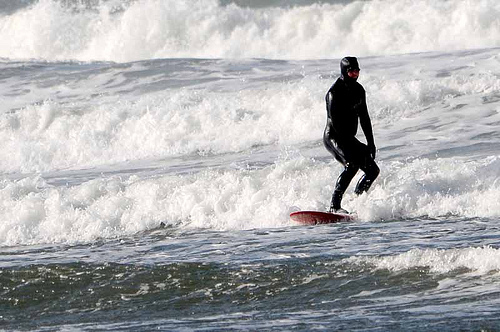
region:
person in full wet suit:
[313, 50, 410, 210]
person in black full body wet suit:
[323, 49, 395, 206]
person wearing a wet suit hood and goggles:
[338, 49, 368, 88]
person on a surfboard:
[282, 44, 403, 232]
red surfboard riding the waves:
[289, 206, 381, 238]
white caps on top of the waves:
[38, 175, 231, 238]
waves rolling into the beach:
[31, 26, 228, 254]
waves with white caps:
[41, 76, 223, 293]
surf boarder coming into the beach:
[274, 41, 406, 246]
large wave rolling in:
[29, 16, 474, 53]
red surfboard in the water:
[285, 203, 377, 235]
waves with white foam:
[32, 74, 168, 184]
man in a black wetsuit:
[317, 46, 398, 220]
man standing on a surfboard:
[286, 52, 386, 236]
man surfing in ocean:
[300, 54, 387, 235]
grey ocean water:
[79, 220, 249, 312]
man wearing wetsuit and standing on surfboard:
[294, 52, 399, 235]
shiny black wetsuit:
[321, 73, 383, 202]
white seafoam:
[114, 100, 241, 224]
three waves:
[60, 11, 262, 243]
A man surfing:
[283, 47, 393, 254]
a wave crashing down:
[28, 162, 498, 224]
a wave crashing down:
[1, 74, 486, 154]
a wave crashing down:
[18, 0, 494, 55]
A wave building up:
[22, 261, 495, 325]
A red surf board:
[286, 205, 401, 231]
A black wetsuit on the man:
[315, 55, 395, 215]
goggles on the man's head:
[340, 60, 365, 75]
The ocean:
[5, 5, 496, 320]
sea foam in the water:
[21, 69, 492, 325]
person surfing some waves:
[127, 35, 440, 262]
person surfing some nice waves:
[145, 25, 450, 280]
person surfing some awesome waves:
[141, 27, 426, 282]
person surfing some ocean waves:
[215, 45, 450, 285]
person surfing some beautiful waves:
[237, 35, 422, 265]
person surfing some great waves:
[220, 36, 425, 276]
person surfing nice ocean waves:
[190, 35, 435, 305]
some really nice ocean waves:
[30, 35, 255, 225]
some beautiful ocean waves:
[10, 26, 260, 243]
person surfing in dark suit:
[275, 38, 403, 245]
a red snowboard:
[289, 205, 364, 225]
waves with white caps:
[0, 240, 499, 315]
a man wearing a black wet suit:
[320, 52, 387, 226]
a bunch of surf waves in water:
[8, 0, 498, 239]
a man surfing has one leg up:
[352, 129, 379, 200]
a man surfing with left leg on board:
[328, 142, 363, 239]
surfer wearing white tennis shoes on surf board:
[311, 197, 357, 219]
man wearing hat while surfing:
[338, 52, 363, 84]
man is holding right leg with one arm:
[344, 82, 405, 157]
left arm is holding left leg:
[317, 88, 362, 180]